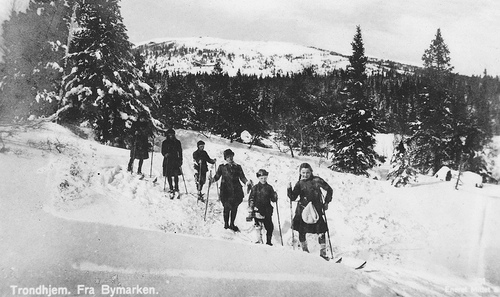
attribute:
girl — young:
[284, 157, 344, 262]